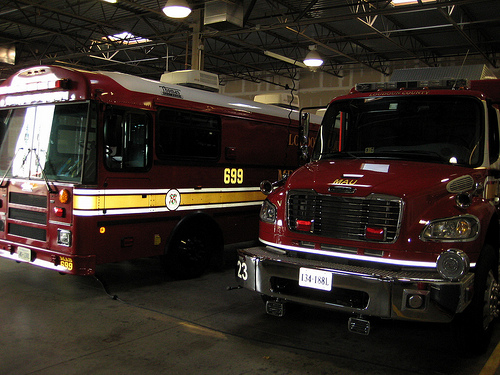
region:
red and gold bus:
[9, 69, 325, 291]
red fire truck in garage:
[261, 81, 498, 338]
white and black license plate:
[300, 265, 332, 294]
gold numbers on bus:
[226, 170, 242, 183]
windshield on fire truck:
[333, 105, 485, 167]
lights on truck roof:
[355, 80, 492, 96]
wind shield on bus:
[2, 107, 80, 175]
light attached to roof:
[163, 3, 190, 19]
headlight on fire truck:
[420, 217, 476, 242]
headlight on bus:
[57, 228, 69, 242]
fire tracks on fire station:
[0, 5, 493, 372]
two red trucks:
[6, 50, 498, 338]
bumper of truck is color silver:
[225, 239, 479, 336]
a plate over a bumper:
[229, 249, 454, 323]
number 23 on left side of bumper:
[225, 240, 474, 328]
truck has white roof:
[6, 48, 324, 285]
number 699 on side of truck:
[1, 61, 306, 276]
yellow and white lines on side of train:
[8, 175, 274, 236]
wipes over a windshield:
[4, 96, 90, 187]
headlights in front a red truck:
[254, 186, 486, 247]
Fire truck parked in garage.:
[226, 63, 498, 345]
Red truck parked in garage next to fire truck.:
[3, 63, 245, 277]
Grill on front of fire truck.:
[279, 186, 405, 249]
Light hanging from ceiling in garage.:
[300, 41, 327, 69]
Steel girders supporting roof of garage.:
[273, 3, 498, 78]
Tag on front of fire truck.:
[293, 262, 338, 296]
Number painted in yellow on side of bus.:
[217, 165, 249, 194]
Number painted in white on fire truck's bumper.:
[230, 256, 255, 287]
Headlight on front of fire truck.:
[419, 212, 482, 242]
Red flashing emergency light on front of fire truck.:
[359, 223, 392, 243]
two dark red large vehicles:
[9, 64, 498, 329]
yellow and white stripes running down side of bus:
[70, 185, 263, 217]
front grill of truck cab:
[283, 185, 399, 237]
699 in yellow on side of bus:
[216, 163, 251, 185]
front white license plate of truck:
[294, 265, 334, 290]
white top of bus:
[96, 74, 328, 124]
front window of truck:
[325, 98, 480, 163]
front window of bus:
[2, 106, 72, 179]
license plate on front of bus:
[15, 245, 50, 256]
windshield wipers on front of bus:
[2, 138, 53, 195]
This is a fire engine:
[276, 168, 378, 240]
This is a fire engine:
[321, 114, 442, 252]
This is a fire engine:
[71, 135, 198, 277]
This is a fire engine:
[15, 45, 219, 156]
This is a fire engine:
[189, 35, 336, 173]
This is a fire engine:
[4, 189, 226, 314]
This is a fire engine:
[187, 178, 404, 309]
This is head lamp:
[411, 210, 483, 250]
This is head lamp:
[421, 246, 476, 286]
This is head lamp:
[244, 198, 301, 238]